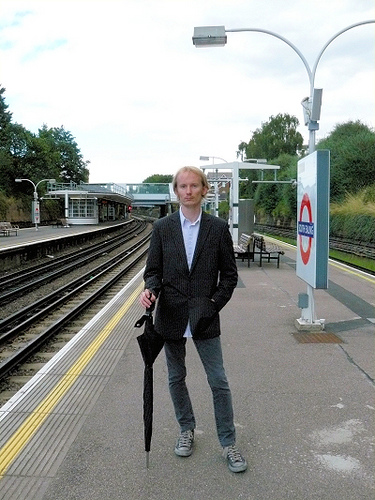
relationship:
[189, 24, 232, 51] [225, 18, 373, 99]
light attached to pole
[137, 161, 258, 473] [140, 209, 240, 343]
man wearing coat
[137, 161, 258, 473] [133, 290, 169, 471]
man holding umbrella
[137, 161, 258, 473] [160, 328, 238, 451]
man wearing jeans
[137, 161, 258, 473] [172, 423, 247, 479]
man wearing shoes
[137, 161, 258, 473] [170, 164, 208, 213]
man has head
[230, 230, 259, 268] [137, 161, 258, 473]
bench behind man